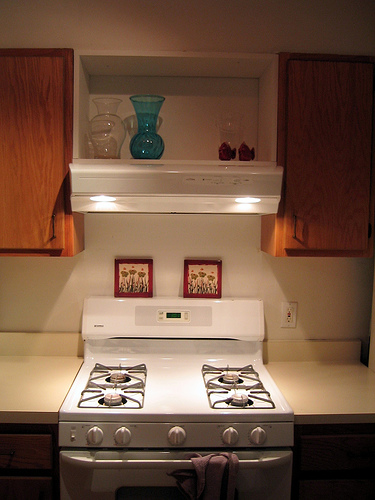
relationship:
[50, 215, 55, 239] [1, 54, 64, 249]
handle on door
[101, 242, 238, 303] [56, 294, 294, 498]
paintings on oven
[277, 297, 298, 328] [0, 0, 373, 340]
outlet on wall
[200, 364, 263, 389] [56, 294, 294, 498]
burner on oven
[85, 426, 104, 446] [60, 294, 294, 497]
knob on oven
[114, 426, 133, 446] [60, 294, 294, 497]
knob on oven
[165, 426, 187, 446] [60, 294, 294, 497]
knob on oven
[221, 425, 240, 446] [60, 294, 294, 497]
knob on oven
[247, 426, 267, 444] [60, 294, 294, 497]
knob on oven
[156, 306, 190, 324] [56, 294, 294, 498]
display on oven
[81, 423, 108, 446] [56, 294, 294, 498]
knob on oven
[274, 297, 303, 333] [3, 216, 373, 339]
plug on wall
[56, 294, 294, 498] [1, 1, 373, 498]
oven in kitchen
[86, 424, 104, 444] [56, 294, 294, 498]
knob on front of oven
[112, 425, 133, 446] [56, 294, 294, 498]
knob on front of oven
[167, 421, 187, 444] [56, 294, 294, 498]
knob on front of oven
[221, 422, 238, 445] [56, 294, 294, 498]
knob on front of oven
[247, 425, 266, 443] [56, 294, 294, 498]
knob on front of oven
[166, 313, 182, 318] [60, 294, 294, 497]
readout on oven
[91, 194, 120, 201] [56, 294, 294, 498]
light above oven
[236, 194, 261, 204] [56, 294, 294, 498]
light above oven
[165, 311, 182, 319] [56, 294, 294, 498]
display on oven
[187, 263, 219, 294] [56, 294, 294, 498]
picture above oven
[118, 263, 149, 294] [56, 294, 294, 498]
picture above oven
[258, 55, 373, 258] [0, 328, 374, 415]
cabinet above countertop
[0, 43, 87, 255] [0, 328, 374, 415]
cabinet above countertop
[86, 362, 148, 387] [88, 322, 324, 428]
burner of stove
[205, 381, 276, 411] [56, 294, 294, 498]
burner of oven